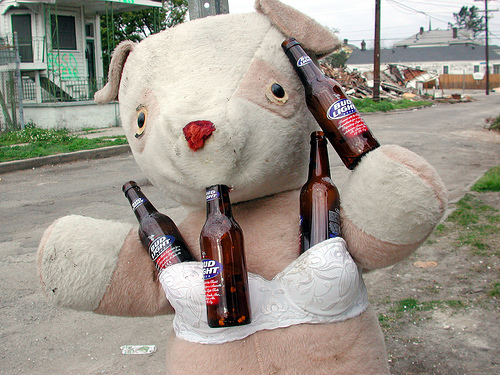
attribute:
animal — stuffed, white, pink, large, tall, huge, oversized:
[35, 0, 447, 374]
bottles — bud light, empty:
[122, 35, 380, 329]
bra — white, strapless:
[157, 236, 366, 344]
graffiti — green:
[44, 50, 80, 84]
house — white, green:
[0, 1, 164, 135]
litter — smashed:
[119, 343, 157, 354]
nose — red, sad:
[182, 120, 217, 151]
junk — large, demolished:
[318, 63, 442, 100]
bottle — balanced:
[282, 37, 380, 170]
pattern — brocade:
[157, 236, 372, 344]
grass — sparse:
[1, 123, 127, 171]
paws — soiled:
[34, 143, 447, 318]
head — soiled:
[93, 0, 339, 212]